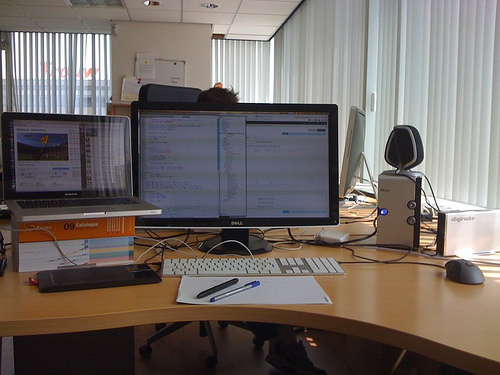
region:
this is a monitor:
[175, 104, 330, 222]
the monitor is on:
[187, 120, 325, 208]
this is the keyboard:
[294, 253, 336, 273]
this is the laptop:
[28, 111, 130, 220]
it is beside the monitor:
[6, 115, 133, 210]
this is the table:
[355, 270, 422, 329]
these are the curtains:
[376, 20, 451, 65]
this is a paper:
[283, 277, 313, 301]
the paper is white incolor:
[273, 277, 310, 299]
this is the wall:
[168, 23, 195, 47]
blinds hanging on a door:
[11, 33, 65, 57]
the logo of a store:
[45, 58, 96, 82]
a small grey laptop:
[11, 107, 156, 230]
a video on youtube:
[15, 130, 65, 161]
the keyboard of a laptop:
[42, 188, 102, 210]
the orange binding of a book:
[18, 221, 130, 242]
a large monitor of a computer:
[144, 102, 344, 236]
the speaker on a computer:
[378, 122, 443, 180]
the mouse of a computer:
[424, 242, 485, 290]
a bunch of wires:
[122, 219, 193, 259]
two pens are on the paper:
[192, 267, 259, 304]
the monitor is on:
[142, 108, 341, 232]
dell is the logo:
[223, 217, 252, 229]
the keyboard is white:
[162, 250, 344, 277]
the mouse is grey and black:
[446, 257, 489, 289]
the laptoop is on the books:
[3, 113, 161, 223]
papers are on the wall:
[127, 46, 169, 78]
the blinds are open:
[8, 33, 113, 110]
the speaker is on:
[375, 167, 426, 248]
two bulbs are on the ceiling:
[143, 2, 221, 15]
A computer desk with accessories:
[3, 93, 498, 358]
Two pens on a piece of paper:
[172, 272, 334, 308]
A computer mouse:
[438, 254, 488, 287]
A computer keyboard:
[159, 251, 347, 279]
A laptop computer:
[2, 108, 167, 225]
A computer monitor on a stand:
[128, 96, 343, 256]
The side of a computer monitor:
[337, 101, 378, 213]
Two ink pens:
[192, 276, 266, 311]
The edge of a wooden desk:
[4, 299, 492, 374]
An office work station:
[5, 5, 495, 372]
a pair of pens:
[193, 272, 265, 308]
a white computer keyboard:
[161, 254, 354, 283]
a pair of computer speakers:
[383, 123, 430, 170]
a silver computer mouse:
[440, 254, 488, 288]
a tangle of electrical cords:
[132, 230, 223, 255]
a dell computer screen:
[124, 98, 351, 234]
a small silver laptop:
[3, 106, 162, 218]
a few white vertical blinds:
[368, 26, 490, 206]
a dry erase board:
[133, 53, 191, 90]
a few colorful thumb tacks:
[135, 77, 142, 87]